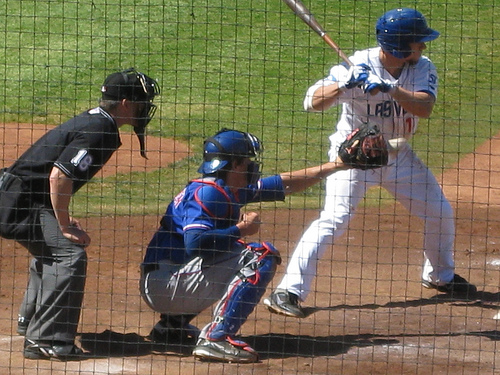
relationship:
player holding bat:
[305, 1, 463, 273] [275, 0, 386, 103]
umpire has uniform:
[3, 53, 159, 374] [15, 108, 111, 316]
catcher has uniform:
[169, 101, 283, 345] [15, 108, 111, 316]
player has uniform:
[305, 1, 463, 273] [311, 49, 460, 279]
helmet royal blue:
[379, 5, 441, 69] [395, 15, 414, 28]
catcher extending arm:
[169, 101, 283, 345] [259, 145, 352, 198]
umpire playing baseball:
[0, 68, 162, 360] [314, 28, 391, 209]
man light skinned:
[305, 1, 463, 273] [401, 92, 423, 108]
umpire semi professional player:
[0, 68, 162, 360] [262, 0, 477, 318]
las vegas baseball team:
[356, 95, 430, 123] [305, 1, 463, 273]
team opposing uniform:
[169, 101, 283, 345] [170, 184, 243, 290]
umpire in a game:
[3, 53, 159, 374] [229, 36, 423, 191]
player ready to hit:
[305, 1, 463, 273] [298, 13, 377, 98]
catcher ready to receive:
[169, 101, 283, 345] [339, 124, 400, 174]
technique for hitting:
[321, 54, 449, 252] [333, 48, 390, 119]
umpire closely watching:
[3, 53, 159, 374] [141, 85, 154, 117]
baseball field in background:
[148, 5, 281, 72] [40, 7, 99, 29]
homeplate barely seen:
[361, 332, 431, 367] [392, 345, 414, 356]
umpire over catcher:
[3, 53, 159, 374] [169, 101, 283, 345]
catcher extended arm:
[169, 101, 283, 345] [259, 145, 352, 198]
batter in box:
[305, 1, 463, 273] [281, 243, 487, 317]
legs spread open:
[310, 198, 464, 227] [345, 202, 432, 285]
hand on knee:
[59, 221, 94, 245] [76, 249, 93, 265]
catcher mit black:
[169, 101, 283, 345] [355, 141, 369, 160]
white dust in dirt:
[489, 257, 500, 270] [469, 200, 497, 227]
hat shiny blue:
[199, 134, 250, 164] [395, 15, 414, 28]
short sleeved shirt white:
[414, 75, 446, 103] [348, 107, 366, 120]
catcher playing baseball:
[169, 101, 283, 345] [314, 28, 391, 209]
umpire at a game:
[3, 53, 159, 374] [229, 36, 423, 191]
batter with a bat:
[305, 1, 463, 273] [275, 0, 386, 103]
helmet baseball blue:
[379, 5, 441, 69] [395, 15, 414, 28]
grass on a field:
[2, 4, 62, 55] [0, 2, 499, 59]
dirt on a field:
[469, 200, 497, 227] [0, 2, 499, 59]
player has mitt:
[169, 101, 283, 345] [329, 132, 397, 160]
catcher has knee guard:
[169, 101, 283, 345] [201, 232, 279, 350]